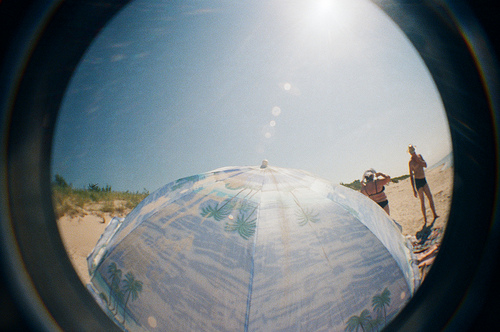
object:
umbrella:
[84, 159, 423, 332]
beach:
[50, 163, 454, 287]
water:
[427, 150, 453, 168]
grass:
[389, 174, 410, 183]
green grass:
[339, 179, 363, 191]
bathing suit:
[364, 180, 388, 209]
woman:
[358, 167, 391, 214]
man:
[408, 144, 441, 223]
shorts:
[414, 177, 427, 191]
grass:
[50, 172, 150, 217]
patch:
[45, 187, 146, 217]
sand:
[55, 164, 455, 283]